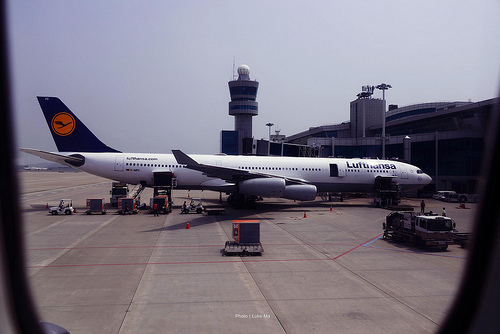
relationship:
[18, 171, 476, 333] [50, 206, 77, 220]
runway has truck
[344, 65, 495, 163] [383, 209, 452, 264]
airport has vehicle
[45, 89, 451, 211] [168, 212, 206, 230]
plane has shadow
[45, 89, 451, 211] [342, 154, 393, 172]
plane has name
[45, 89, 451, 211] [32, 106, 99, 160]
plane has tail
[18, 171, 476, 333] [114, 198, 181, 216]
runway has luggage cart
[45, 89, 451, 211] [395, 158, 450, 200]
plane has cockpit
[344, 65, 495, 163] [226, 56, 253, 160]
airport has tower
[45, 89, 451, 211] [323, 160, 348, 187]
plane has door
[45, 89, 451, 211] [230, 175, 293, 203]
plane has engine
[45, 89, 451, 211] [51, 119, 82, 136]
plane has logo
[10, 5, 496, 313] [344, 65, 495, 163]
photo of airport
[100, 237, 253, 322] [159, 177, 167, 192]
runway has baggage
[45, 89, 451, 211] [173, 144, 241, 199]
plane has wing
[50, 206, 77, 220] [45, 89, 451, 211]
truck next to plane